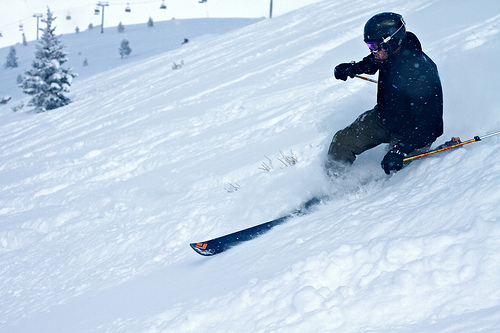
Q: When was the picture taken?
A: During the daytime.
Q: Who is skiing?
A: The man.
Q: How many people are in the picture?
A: One person.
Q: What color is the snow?
A: White.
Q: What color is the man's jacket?
A: Black.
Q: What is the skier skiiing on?
A: Snow.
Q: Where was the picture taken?
A: On a hill.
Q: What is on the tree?
A: Snow.